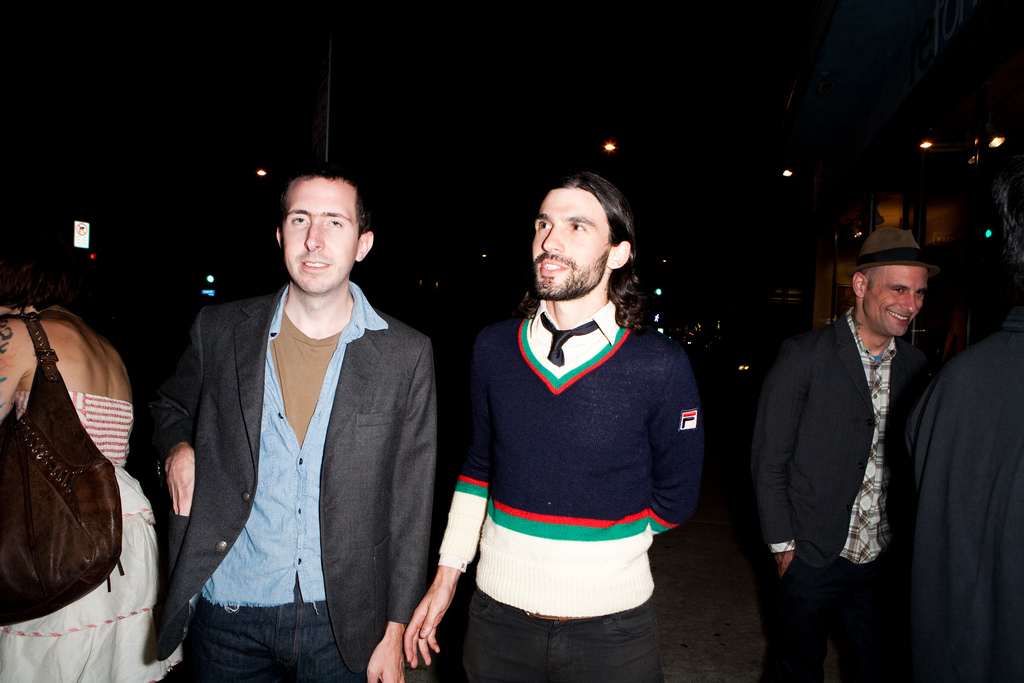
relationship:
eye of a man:
[566, 216, 587, 237] [744, 226, 931, 683]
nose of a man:
[892, 294, 937, 321] [744, 207, 970, 679]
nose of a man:
[533, 224, 572, 254] [397, 161, 712, 680]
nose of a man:
[298, 220, 333, 255] [146, 163, 444, 679]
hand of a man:
[397, 576, 458, 672] [397, 161, 712, 680]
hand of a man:
[361, 629, 412, 680] [397, 161, 712, 680]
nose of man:
[542, 224, 565, 255] [387, 137, 720, 669]